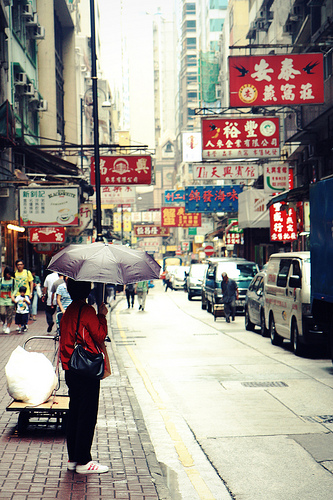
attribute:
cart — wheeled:
[207, 289, 233, 320]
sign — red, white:
[199, 113, 279, 161]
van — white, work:
[261, 248, 320, 353]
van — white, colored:
[200, 254, 257, 331]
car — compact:
[246, 268, 269, 329]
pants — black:
[64, 368, 99, 461]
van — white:
[262, 249, 326, 357]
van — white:
[263, 250, 330, 360]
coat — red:
[57, 316, 110, 364]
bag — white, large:
[4, 341, 62, 410]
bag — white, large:
[65, 332, 110, 386]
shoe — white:
[66, 461, 76, 470]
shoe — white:
[76, 461, 109, 474]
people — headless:
[122, 274, 151, 314]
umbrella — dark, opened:
[49, 237, 163, 285]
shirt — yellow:
[12, 266, 35, 305]